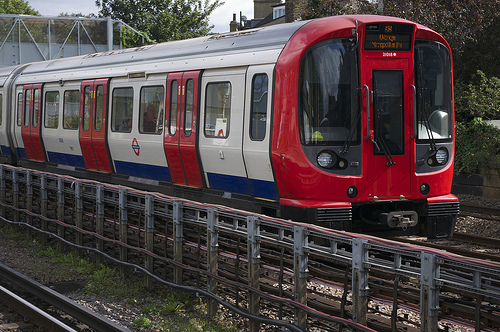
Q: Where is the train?
A: On the tracks.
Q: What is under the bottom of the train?
A: The tracks.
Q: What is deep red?
A: The color of the train.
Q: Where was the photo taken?
A: In the United Kingdom.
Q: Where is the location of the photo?
A: London.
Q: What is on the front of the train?
A: Windshields.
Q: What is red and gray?
A: The passenger train.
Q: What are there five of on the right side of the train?
A: Passenger windows.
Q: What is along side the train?
A: A fence.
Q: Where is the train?
A: On tracks.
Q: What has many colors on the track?
A: A train.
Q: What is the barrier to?
A: Subway tracks.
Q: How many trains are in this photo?
A: One.